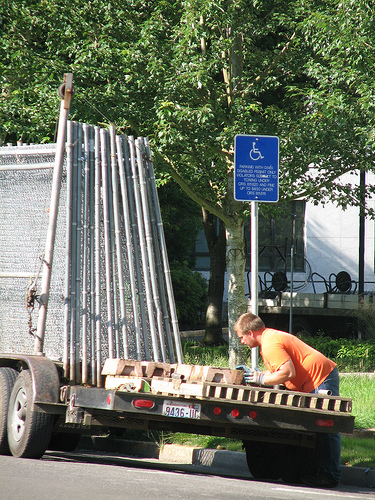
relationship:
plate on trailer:
[161, 394, 204, 425] [73, 357, 358, 450]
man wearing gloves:
[235, 314, 338, 398] [244, 367, 264, 388]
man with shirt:
[235, 314, 338, 398] [261, 330, 334, 388]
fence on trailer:
[59, 119, 179, 369] [73, 357, 358, 450]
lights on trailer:
[129, 397, 159, 415] [73, 357, 358, 450]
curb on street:
[128, 440, 194, 464] [8, 449, 187, 499]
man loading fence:
[235, 314, 338, 398] [59, 119, 179, 369]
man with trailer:
[235, 314, 338, 398] [73, 357, 358, 450]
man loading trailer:
[235, 314, 338, 398] [73, 357, 358, 450]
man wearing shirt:
[235, 314, 338, 398] [261, 330, 334, 388]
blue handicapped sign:
[238, 139, 247, 151] [231, 132, 280, 203]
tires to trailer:
[0, 361, 50, 464] [73, 357, 358, 450]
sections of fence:
[1, 149, 64, 355] [59, 119, 179, 369]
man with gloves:
[235, 314, 338, 398] [244, 367, 264, 388]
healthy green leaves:
[94, 27, 112, 43] [290, 17, 355, 70]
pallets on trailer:
[104, 356, 241, 401] [73, 357, 358, 450]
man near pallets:
[235, 314, 338, 398] [104, 356, 241, 401]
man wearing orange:
[235, 314, 338, 398] [297, 355, 316, 371]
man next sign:
[235, 314, 338, 398] [231, 132, 280, 203]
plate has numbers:
[161, 394, 204, 425] [166, 406, 183, 420]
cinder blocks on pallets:
[100, 359, 250, 386] [104, 356, 241, 401]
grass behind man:
[350, 375, 370, 396] [235, 314, 338, 398]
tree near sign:
[212, 207, 250, 320] [231, 132, 280, 203]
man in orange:
[235, 314, 338, 398] [297, 355, 316, 371]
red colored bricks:
[106, 361, 117, 373] [104, 358, 144, 386]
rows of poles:
[62, 120, 77, 379] [57, 115, 172, 340]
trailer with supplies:
[73, 357, 358, 450] [7, 119, 200, 387]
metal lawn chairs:
[67, 163, 89, 192] [332, 269, 354, 291]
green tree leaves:
[311, 18, 336, 32] [290, 17, 355, 70]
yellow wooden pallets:
[148, 365, 154, 377] [104, 356, 241, 401]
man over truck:
[235, 314, 338, 398] [5, 375, 355, 459]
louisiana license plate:
[165, 400, 188, 410] [161, 394, 204, 425]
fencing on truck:
[2, 145, 59, 351] [5, 375, 355, 459]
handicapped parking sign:
[245, 139, 267, 160] [231, 132, 280, 203]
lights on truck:
[129, 397, 159, 415] [5, 375, 355, 459]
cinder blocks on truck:
[100, 359, 250, 386] [5, 375, 355, 459]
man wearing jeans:
[235, 314, 338, 398] [327, 377, 343, 394]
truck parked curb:
[5, 375, 355, 459] [128, 440, 194, 464]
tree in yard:
[212, 207, 250, 320] [202, 337, 369, 377]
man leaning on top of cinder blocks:
[235, 314, 338, 398] [100, 359, 250, 386]